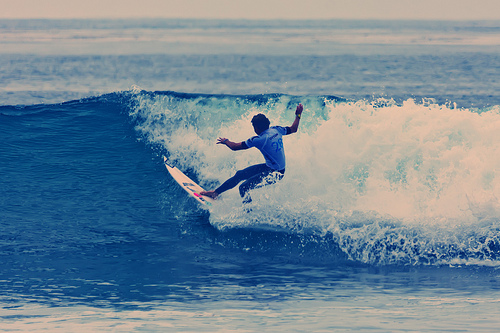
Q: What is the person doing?
A: Surfing.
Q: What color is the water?
A: Blue.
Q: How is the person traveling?
A: By surfboard.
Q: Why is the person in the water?
A: To surf.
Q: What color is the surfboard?
A: White.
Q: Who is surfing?
A: A man.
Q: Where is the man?
A: In the water.